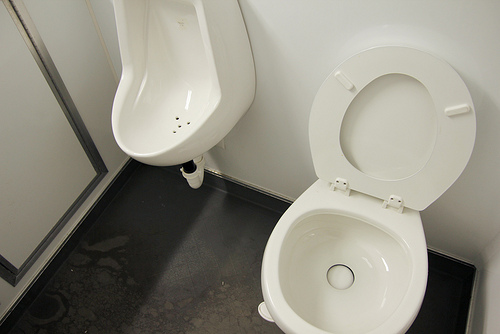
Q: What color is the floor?
A: Dark gray.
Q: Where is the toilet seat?
A: Pushed up.